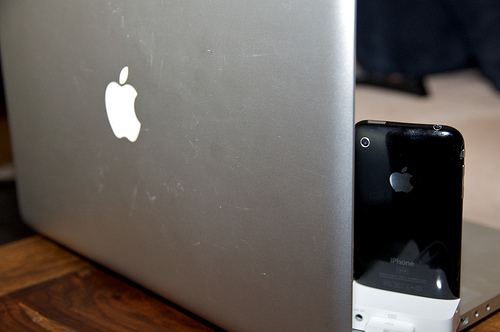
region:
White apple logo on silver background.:
[102, 65, 143, 143]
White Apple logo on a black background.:
[387, 161, 412, 192]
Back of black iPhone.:
[350, 115, 460, 295]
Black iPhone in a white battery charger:
[350, 115, 460, 325]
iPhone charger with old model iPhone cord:
[350, 275, 460, 326]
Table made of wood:
[0, 242, 66, 327]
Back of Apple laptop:
[0, 0, 352, 330]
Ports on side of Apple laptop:
[473, 303, 492, 318]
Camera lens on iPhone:
[358, 136, 372, 149]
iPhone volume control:
[459, 161, 463, 209]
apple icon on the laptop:
[78, 53, 157, 159]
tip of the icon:
[99, 49, 146, 96]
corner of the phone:
[423, 111, 476, 169]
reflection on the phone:
[370, 218, 442, 286]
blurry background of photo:
[371, 16, 486, 95]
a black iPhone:
[343, 98, 470, 308]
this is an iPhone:
[347, 97, 484, 312]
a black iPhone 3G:
[334, 86, 478, 301]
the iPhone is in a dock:
[337, 94, 490, 327]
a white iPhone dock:
[340, 275, 467, 330]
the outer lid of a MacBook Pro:
[0, 1, 378, 330]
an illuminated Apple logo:
[91, 55, 158, 150]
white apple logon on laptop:
[95, 67, 146, 145]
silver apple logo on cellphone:
[387, 165, 414, 192]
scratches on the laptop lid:
[10, 12, 322, 235]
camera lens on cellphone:
[360, 134, 372, 144]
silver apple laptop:
[3, 0, 499, 330]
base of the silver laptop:
[451, 214, 499, 319]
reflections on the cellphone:
[363, 123, 455, 288]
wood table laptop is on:
[9, 225, 491, 329]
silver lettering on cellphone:
[387, 254, 418, 271]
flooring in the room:
[365, 67, 498, 232]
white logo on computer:
[83, 54, 153, 186]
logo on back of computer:
[83, 45, 155, 152]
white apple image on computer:
[91, 58, 146, 149]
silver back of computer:
[6, 6, 350, 329]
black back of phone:
[353, 128, 457, 298]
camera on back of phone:
[361, 131, 371, 148]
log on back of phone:
[389, 159, 422, 193]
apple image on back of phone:
[389, 157, 422, 195]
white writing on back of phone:
[380, 244, 416, 275]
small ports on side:
[463, 302, 495, 327]